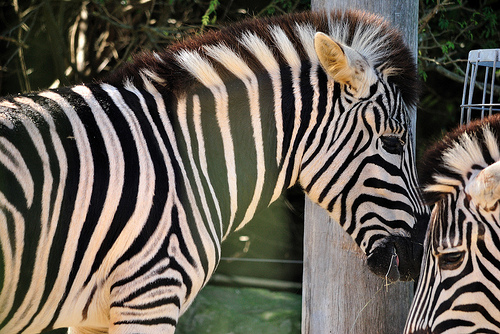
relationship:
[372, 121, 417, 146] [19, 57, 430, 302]
eyes on zebra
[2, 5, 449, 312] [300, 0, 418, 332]
zebra by pole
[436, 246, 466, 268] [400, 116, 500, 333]
eye on zebra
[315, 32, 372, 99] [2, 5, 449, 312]
ear on zebra